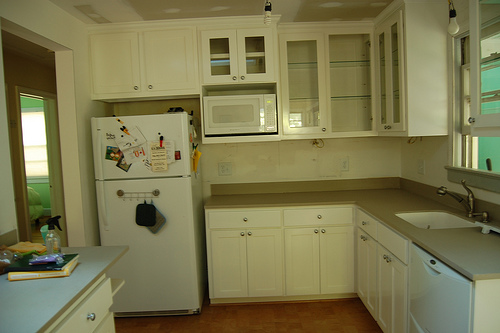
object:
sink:
[391, 180, 483, 242]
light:
[443, 6, 462, 38]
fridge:
[85, 110, 203, 316]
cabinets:
[87, 26, 200, 101]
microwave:
[201, 92, 282, 137]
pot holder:
[132, 201, 159, 235]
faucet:
[433, 183, 449, 201]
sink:
[388, 211, 480, 231]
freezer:
[89, 109, 194, 182]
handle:
[93, 137, 111, 228]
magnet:
[158, 140, 163, 147]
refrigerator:
[89, 112, 205, 317]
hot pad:
[134, 201, 158, 229]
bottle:
[45, 231, 62, 251]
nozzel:
[45, 212, 66, 225]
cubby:
[91, 26, 202, 100]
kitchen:
[0, 0, 497, 331]